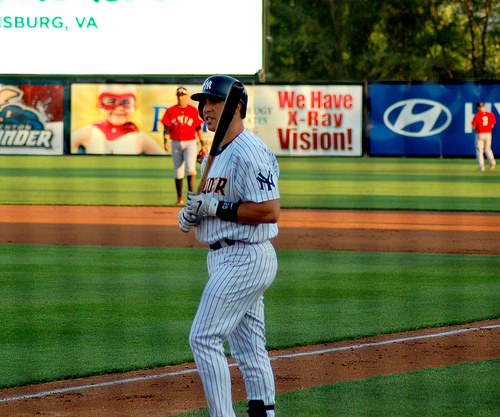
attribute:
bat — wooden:
[180, 82, 244, 234]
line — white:
[0, 324, 499, 404]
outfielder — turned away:
[471, 102, 496, 173]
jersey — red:
[471, 111, 495, 133]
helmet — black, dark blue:
[190, 76, 248, 122]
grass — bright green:
[1, 154, 499, 416]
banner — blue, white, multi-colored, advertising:
[367, 81, 499, 159]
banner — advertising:
[69, 83, 365, 158]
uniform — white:
[189, 127, 278, 416]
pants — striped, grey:
[188, 239, 278, 416]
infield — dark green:
[0, 243, 499, 415]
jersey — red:
[163, 104, 204, 141]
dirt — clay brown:
[1, 205, 500, 416]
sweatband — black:
[216, 200, 240, 224]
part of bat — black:
[209, 81, 243, 156]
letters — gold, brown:
[202, 176, 228, 194]